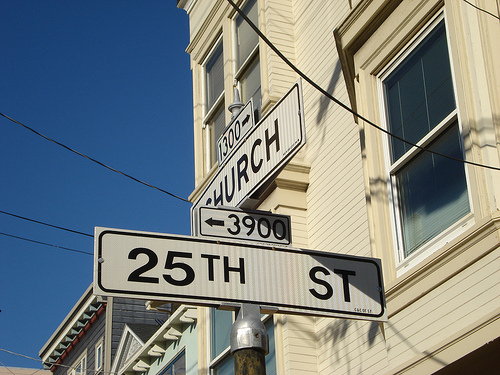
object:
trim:
[380, 206, 486, 273]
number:
[240, 214, 256, 235]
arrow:
[204, 217, 224, 227]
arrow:
[237, 113, 251, 125]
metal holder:
[47, 157, 437, 375]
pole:
[227, 323, 267, 374]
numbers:
[354, 307, 381, 316]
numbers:
[161, 250, 195, 287]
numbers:
[234, 119, 240, 140]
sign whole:
[96, 81, 389, 373]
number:
[272, 219, 287, 240]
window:
[347, 0, 475, 265]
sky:
[0, 0, 187, 364]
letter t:
[201, 253, 221, 282]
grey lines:
[258, 252, 308, 302]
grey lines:
[276, 104, 295, 141]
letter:
[309, 266, 334, 302]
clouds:
[8, 227, 75, 312]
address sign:
[91, 225, 386, 321]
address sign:
[193, 204, 293, 249]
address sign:
[186, 79, 305, 209]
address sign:
[217, 99, 255, 161]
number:
[228, 213, 240, 235]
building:
[32, 0, 500, 375]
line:
[24, 144, 167, 188]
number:
[256, 215, 271, 238]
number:
[126, 248, 159, 282]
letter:
[222, 255, 246, 285]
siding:
[279, 24, 376, 245]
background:
[17, 139, 256, 277]